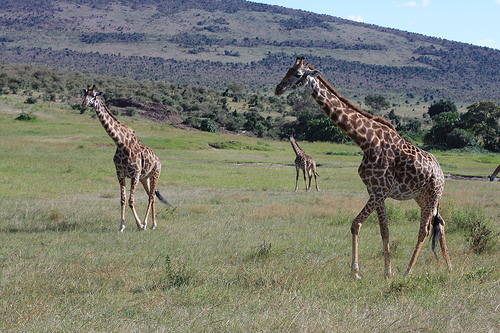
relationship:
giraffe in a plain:
[90, 93, 160, 189] [19, 182, 202, 316]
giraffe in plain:
[272, 53, 458, 292] [0, 63, 495, 331]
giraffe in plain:
[286, 135, 320, 194] [0, 63, 495, 331]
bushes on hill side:
[92, 78, 114, 89] [0, 0, 496, 150]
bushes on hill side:
[127, 107, 136, 114] [0, 0, 496, 150]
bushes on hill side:
[152, 91, 175, 105] [0, 0, 496, 150]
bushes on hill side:
[240, 114, 269, 132] [0, 0, 496, 150]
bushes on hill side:
[185, 115, 216, 132] [0, 0, 496, 150]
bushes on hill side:
[171, 90, 238, 129] [0, 0, 496, 150]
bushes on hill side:
[91, 12, 192, 104] [0, 0, 496, 150]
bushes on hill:
[72, 27, 146, 45] [0, 3, 497, 152]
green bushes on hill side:
[149, 46, 213, 123] [0, 0, 496, 150]